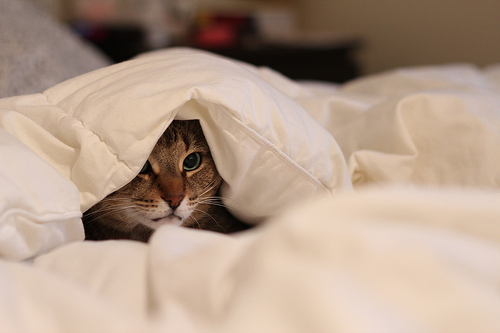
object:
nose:
[154, 177, 196, 210]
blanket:
[25, 59, 463, 226]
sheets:
[0, 43, 499, 332]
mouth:
[149, 206, 192, 230]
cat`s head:
[82, 116, 222, 233]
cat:
[80, 118, 258, 244]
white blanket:
[0, 43, 499, 333]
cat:
[82, 117, 254, 240]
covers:
[22, 63, 348, 245]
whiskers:
[188, 188, 226, 230]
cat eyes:
[180, 149, 207, 172]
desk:
[167, 32, 369, 83]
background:
[0, 0, 498, 73]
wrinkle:
[342, 85, 460, 188]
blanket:
[1, 43, 498, 330]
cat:
[134, 125, 224, 221]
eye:
[179, 150, 209, 173]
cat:
[85, 115, 230, 245]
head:
[90, 120, 218, 229]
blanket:
[257, 101, 443, 284]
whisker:
[83, 202, 136, 217]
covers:
[0, 36, 497, 330]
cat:
[81, 113, 245, 246]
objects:
[113, 4, 304, 44]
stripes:
[167, 121, 185, 145]